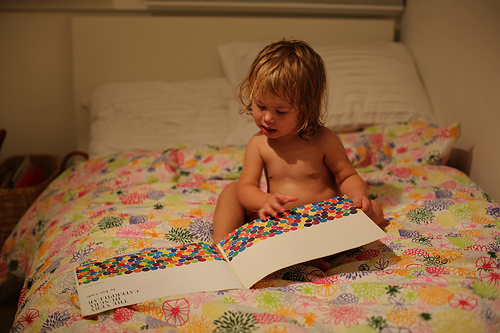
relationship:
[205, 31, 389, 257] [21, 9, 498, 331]
child on bed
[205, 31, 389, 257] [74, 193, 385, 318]
child reading book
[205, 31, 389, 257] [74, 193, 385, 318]
child on book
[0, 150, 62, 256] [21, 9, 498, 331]
basket on bed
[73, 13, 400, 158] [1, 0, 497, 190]
panel on wall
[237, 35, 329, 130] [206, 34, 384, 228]
blonde hair on child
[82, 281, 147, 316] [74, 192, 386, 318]
words on children's book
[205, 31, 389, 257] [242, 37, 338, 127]
child on hair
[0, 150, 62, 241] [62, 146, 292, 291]
basket on bed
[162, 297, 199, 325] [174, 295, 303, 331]
flower on comforter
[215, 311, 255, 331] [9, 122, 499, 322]
flower on comforter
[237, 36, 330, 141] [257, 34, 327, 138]
blonde hair on head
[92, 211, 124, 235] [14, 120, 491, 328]
flower on bread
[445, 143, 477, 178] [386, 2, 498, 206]
shadow on wall